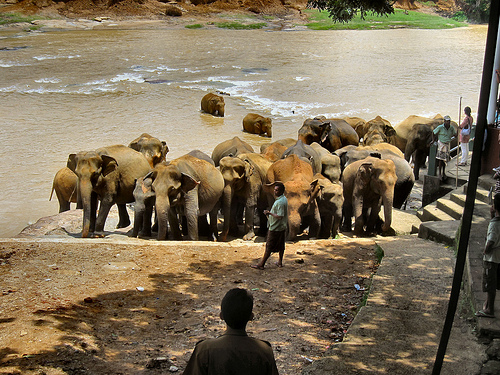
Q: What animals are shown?
A: Elephants.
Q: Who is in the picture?
A: A woman and three men.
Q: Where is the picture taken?
A: A river.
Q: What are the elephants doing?
A: Crossing river.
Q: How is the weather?
A: Clear.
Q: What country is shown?
A: India.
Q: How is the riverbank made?
A: Of dirt.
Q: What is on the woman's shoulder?
A: A bag.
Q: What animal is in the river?
A: Elephants.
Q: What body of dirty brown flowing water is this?
A: River.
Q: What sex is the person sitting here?
A: Male.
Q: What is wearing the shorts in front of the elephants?
A: The guy.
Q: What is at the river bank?
A: The group of elephants.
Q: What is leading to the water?
A: The cement walkway.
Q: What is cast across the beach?
A: Shadows from the trees.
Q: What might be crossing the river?
A: These elephants.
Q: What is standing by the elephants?
A: The man.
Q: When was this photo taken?
A: In the daytime.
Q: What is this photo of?
A: A river.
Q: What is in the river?
A: Elephants.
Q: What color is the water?
A: Brown.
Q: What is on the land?
A: Dirt.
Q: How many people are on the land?
A: Two.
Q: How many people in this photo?
A: Four.